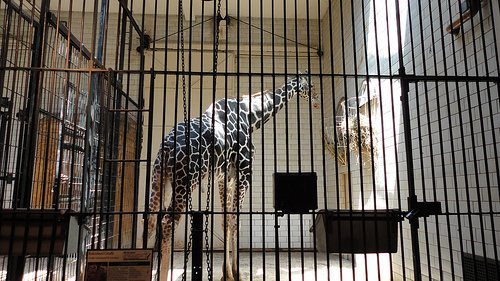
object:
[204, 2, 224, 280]
chain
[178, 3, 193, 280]
chain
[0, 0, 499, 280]
cage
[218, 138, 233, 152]
spot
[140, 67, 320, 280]
giraffe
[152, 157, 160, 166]
spot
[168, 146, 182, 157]
spot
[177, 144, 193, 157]
spot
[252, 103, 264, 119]
spot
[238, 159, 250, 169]
spot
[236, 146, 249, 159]
spot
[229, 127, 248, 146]
spot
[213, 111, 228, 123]
spot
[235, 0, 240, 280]
bar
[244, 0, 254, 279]
bar